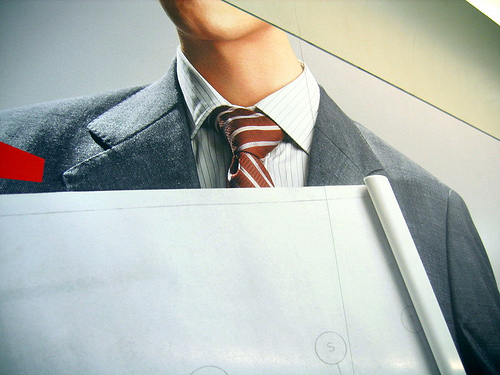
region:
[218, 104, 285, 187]
red and white striped necktie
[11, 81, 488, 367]
gray suit jacket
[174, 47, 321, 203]
pinstriped dress shirt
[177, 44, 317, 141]
collar of the dress shirt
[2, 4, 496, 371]
advertisement on the wall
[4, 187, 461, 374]
paper man is holding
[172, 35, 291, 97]
neck of the man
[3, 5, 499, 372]
man dressed in business suit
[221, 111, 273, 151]
knot of the necktie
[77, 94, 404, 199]
lapels of the gray suit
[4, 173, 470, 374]
A set of blueprints.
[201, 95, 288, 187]
A brown and white tie.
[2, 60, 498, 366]
A grey suit jacket.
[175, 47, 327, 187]
A striped dress shirt.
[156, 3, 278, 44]
A person's chin.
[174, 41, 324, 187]
A white dress shirt with a brown tie.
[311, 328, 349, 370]
The letter S inside a circle.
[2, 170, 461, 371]
A white piece of paper rolled at the end.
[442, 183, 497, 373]
The sleeve of a suit jacket.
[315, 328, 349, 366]
A circle on a piece of paper.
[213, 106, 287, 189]
a red and white striped tie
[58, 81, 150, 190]
stitching on the edge of the suit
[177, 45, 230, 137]
collar of a striped shirt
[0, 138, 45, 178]
solid red object on the left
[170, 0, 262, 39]
chin of a man in a suit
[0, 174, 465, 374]
a scroll of paper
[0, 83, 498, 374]
a light gray man's suit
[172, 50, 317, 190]
dress shirt being worn by a man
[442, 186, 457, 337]
seam where the arm is attached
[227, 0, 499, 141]
a glass shield in the upper corner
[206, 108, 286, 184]
man wearing a necktie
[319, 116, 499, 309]
man wearing a gray jacket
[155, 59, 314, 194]
man wearing dress shirt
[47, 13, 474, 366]
man on a billboard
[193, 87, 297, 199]
red and silver necktie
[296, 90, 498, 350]
gray suit jacket on the billboard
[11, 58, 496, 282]
Man wearing in a suit jacket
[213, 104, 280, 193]
tie around the man's neck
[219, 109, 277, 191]
tie on the shirt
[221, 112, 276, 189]
striped tie on the shirt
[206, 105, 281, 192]
striped tie around the man's neck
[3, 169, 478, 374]
paper in front of man's chest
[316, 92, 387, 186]
collar on the jacket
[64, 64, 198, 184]
collar on the jacket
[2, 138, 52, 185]
red strip of material on the picture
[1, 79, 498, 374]
suit jacket on the man's body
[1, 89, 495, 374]
gray suit jacket on the man's body